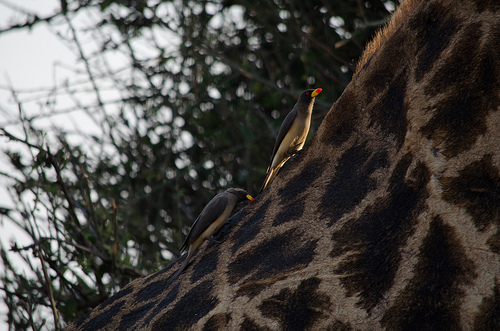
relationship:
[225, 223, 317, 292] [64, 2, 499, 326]
brown spot on giraffe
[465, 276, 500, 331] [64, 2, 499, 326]
spot on giraffe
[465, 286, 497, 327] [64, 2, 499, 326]
spot on giraffe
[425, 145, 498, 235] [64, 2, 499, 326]
spot on giraffe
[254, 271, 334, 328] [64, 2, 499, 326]
spot on giraffe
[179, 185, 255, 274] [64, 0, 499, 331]
bird on back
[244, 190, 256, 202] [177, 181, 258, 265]
beak of bird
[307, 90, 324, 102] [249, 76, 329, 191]
beak of bird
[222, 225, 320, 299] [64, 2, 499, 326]
spot of giraffe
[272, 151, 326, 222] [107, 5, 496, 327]
spot of giraffe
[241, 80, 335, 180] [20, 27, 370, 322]
bird on back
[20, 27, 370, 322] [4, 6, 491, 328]
back of giraffe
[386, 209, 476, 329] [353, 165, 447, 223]
spot of giraffe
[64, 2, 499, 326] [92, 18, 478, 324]
giraffe has spots